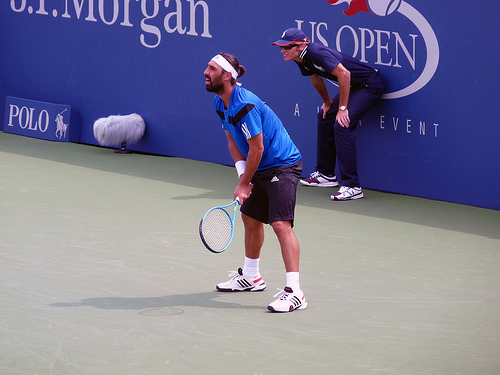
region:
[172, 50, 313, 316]
a man holding a tennis racket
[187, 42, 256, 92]
a man wearing a white headband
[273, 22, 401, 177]
a man holding his two hands on his knees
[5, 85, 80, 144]
a blue advertisement for Polo on the wall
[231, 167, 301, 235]
a man wearing black shirts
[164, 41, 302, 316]
a man playing tennis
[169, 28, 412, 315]
two men standing on a tennis court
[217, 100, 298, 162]
man wearing a blue shirt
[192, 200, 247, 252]
a blue tennis racket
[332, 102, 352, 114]
a gold wristwatch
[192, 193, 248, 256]
Tennis racket is blue and black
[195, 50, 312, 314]
Man playing tennis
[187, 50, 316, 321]
Man wearing blue shirt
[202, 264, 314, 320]
Man wearing white shoes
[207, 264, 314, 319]
Black stripes on shoes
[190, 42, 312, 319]
Man wearing black shorts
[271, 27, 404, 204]
Man wearing blue and red hat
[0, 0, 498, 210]
The wall is blue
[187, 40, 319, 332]
Man wearing white headband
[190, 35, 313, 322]
Man wearing white wristband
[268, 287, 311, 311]
right black and white tennis shoe of tennis player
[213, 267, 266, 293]
left black and white tennis shoe of tennis player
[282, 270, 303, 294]
white, right sock of tennis player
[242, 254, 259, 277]
left white sock of tennis player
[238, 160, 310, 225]
black shorts of tennis player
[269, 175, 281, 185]
emblem on tennis players shorts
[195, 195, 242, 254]
tennis players tennis racquet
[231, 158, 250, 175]
sweat band on tennis players left arm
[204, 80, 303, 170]
blue shirt of tennis player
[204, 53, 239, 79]
sweat band on tennis players head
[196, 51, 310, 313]
a male tennis player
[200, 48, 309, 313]
a man carrying a tennis racket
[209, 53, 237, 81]
a tennis player's sweat band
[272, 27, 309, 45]
a man's blue cap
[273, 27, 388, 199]
a ball boy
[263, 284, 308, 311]
a man's white tennis shoe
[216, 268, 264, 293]
a man's right shoe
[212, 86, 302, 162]
a blue shirt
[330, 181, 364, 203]
a man's left tennis shoe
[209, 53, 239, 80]
Headband on head is white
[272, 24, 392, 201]
Man leaning against blue wall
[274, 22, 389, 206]
Man wearing hat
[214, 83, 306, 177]
Shirt is blue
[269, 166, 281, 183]
Adidas logo on black shorts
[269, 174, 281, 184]
Adidas logo is white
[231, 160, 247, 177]
Wristband is white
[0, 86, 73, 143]
POLO sign leaning against blue wall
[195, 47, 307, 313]
Man has beard